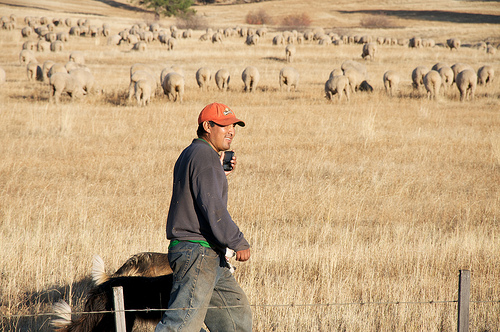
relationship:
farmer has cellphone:
[156, 105, 255, 330] [223, 150, 235, 170]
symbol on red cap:
[218, 102, 234, 116] [196, 102, 244, 129]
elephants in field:
[323, 74, 349, 104] [1, 10, 498, 329]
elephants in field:
[276, 64, 303, 89] [1, 10, 498, 329]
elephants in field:
[239, 65, 260, 91] [1, 10, 498, 329]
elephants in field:
[193, 67, 213, 88] [1, 10, 498, 329]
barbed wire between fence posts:
[129, 295, 457, 311] [105, 278, 130, 328]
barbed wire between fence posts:
[129, 295, 457, 311] [452, 265, 482, 328]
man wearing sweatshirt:
[155, 102, 263, 331] [167, 140, 247, 258]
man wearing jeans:
[155, 99, 263, 327] [154, 237, 255, 329]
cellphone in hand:
[220, 148, 237, 170] [223, 151, 236, 169]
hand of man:
[223, 151, 236, 169] [162, 105, 263, 330]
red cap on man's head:
[196, 100, 245, 129] [188, 100, 249, 152]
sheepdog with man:
[47, 260, 235, 330] [155, 102, 263, 331]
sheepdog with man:
[89, 245, 236, 284] [155, 102, 263, 331]